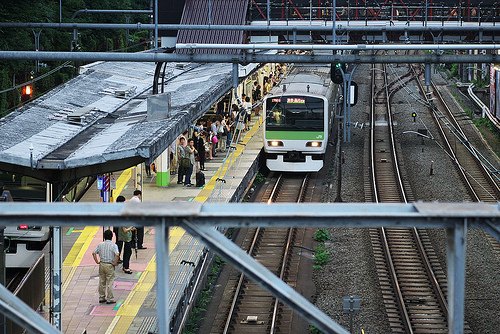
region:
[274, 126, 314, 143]
lime green stripe on front of train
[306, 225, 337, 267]
weeds along the train tracks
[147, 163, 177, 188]
lime green at the bottom of pole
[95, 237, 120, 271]
man has his hands on his hips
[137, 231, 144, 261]
woman holding an umbrella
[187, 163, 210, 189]
rolling bag in front of the man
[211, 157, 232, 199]
yellow line on the platform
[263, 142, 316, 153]
two lights are on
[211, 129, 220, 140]
woman is holding a purse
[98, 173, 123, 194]
red and white strips on the pole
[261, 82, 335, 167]
this is a train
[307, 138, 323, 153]
this is the lump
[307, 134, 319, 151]
the lump is on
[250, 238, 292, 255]
this is the railway line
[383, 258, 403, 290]
this is a metal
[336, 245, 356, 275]
these are small rocks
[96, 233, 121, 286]
this is a man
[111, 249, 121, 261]
the man is light skinned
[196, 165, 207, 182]
this is a bag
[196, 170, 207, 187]
the bag is black in color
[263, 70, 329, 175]
a white and green train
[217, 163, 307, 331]
a set of train tracks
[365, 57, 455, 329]
a set of train tracks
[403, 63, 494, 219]
a set of train tracks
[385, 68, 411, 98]
a set of train tracks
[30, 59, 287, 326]
a train boarding platform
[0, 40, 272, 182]
a boarding platform overhead shelter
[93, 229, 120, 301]
a man standing on platform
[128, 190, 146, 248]
a man standing on platform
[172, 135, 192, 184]
a man standing on platform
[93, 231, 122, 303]
A person waiting for the train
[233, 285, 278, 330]
Train tracks in front of the train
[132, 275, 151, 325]
A yellow line at the train station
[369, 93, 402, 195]
Train tracks beside the train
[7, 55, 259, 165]
The roof of the train station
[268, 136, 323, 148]
Headlights on the train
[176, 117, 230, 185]
People waiting for the train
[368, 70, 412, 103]
A curve in the train tracks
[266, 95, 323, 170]
The front of the train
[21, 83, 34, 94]
A bright light near the train station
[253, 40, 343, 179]
train at a train station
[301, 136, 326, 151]
front head light on a train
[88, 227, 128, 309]
person with tan pants standing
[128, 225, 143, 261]
umbrella in a persons hand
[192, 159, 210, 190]
suitcase on the ground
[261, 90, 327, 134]
front windshield on a train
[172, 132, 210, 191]
people standing at a train station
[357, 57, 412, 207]
train tracks on the ground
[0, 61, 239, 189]
roof over a train platform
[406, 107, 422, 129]
green light on the ground between train tracks